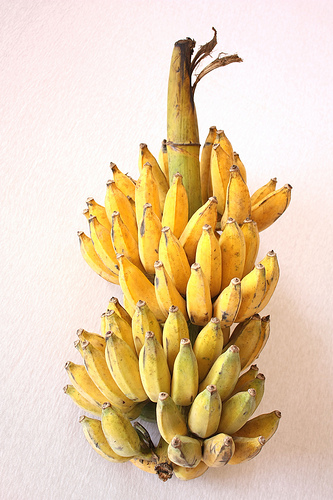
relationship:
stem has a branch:
[164, 38, 203, 220] [193, 24, 240, 92]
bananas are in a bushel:
[64, 125, 292, 483] [64, 126, 291, 484]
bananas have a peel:
[64, 125, 292, 483] [252, 185, 292, 231]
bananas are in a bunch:
[64, 125, 292, 483] [64, 123, 292, 483]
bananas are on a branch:
[64, 125, 292, 483] [193, 24, 240, 92]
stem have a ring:
[164, 38, 203, 220] [168, 140, 200, 152]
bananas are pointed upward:
[64, 125, 292, 483] [84, 127, 291, 215]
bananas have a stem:
[64, 125, 292, 483] [164, 38, 203, 220]